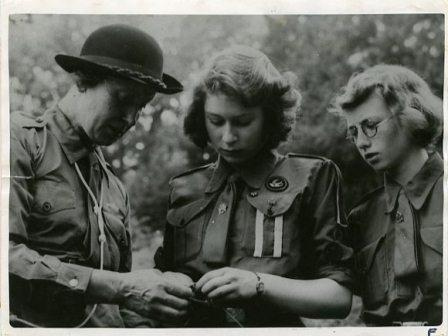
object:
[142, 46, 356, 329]
woman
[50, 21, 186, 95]
trilbyhat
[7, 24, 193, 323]
man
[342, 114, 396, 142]
glasses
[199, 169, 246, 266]
tie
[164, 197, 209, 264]
pocket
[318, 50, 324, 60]
leaves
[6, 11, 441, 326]
scene